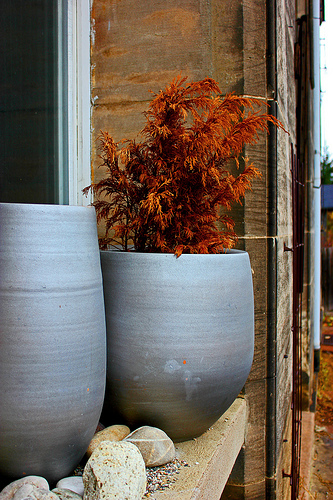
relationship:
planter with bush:
[101, 246, 256, 445] [86, 68, 293, 255]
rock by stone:
[80, 438, 150, 500] [127, 425, 178, 470]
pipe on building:
[305, 0, 321, 352] [1, 0, 310, 498]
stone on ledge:
[127, 425, 178, 470] [149, 393, 247, 500]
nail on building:
[282, 242, 308, 254] [1, 0, 310, 498]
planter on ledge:
[101, 246, 256, 445] [149, 393, 247, 500]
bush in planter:
[86, 68, 293, 255] [101, 246, 256, 445]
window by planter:
[0, 1, 90, 203] [101, 246, 256, 445]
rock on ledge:
[80, 438, 150, 500] [149, 393, 247, 500]